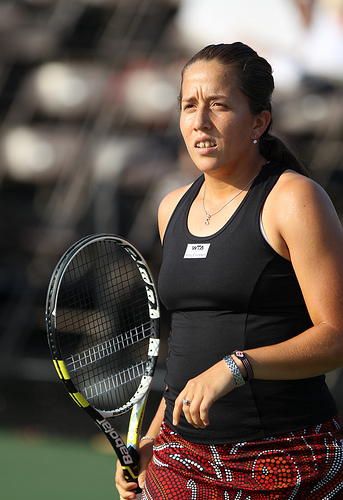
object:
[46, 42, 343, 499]
woman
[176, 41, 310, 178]
hair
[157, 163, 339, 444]
shirt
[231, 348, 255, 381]
bracelet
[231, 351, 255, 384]
watch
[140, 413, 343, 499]
shorts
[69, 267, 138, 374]
strings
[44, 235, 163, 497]
tennis racket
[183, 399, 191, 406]
ring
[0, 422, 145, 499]
tennis court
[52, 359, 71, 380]
yellow stripes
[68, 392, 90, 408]
yellow stripes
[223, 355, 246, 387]
bracelet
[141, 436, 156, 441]
bracelet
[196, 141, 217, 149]
mouth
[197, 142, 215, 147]
teeth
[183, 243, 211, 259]
label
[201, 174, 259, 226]
necklace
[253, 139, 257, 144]
earring